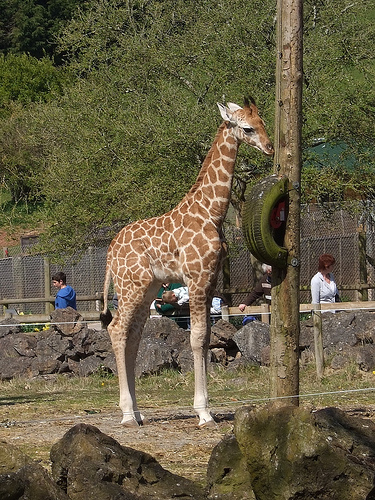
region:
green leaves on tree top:
[0, 53, 65, 109]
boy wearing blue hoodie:
[51, 271, 77, 307]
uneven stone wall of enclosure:
[0, 309, 373, 380]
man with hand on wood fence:
[222, 265, 271, 323]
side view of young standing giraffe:
[101, 93, 272, 427]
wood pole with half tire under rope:
[239, 0, 303, 402]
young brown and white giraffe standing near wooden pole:
[96, 90, 280, 433]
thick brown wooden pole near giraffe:
[267, 0, 307, 447]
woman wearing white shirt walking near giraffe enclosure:
[307, 250, 341, 320]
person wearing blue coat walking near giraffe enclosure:
[50, 267, 78, 322]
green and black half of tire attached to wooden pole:
[238, 171, 291, 270]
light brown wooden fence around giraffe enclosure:
[0, 298, 374, 388]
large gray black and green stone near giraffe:
[199, 397, 374, 498]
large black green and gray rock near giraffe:
[45, 420, 211, 498]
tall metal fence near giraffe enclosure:
[1, 223, 374, 325]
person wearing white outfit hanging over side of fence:
[160, 281, 211, 313]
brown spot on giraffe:
[115, 227, 124, 243]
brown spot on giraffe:
[124, 231, 132, 244]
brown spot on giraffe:
[131, 225, 147, 238]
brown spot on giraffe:
[130, 235, 152, 253]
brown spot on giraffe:
[116, 244, 132, 257]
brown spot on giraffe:
[140, 252, 151, 270]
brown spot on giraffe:
[131, 263, 140, 272]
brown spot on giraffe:
[184, 244, 200, 263]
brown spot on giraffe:
[180, 212, 203, 231]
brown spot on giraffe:
[190, 283, 196, 293]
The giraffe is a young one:
[92, 94, 289, 411]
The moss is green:
[234, 402, 328, 484]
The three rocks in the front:
[3, 407, 370, 493]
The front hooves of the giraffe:
[196, 409, 216, 432]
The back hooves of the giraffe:
[121, 409, 139, 427]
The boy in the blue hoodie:
[43, 271, 79, 312]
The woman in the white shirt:
[307, 244, 354, 305]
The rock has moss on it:
[227, 387, 347, 481]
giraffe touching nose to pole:
[191, 90, 302, 177]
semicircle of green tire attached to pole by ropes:
[240, 3, 300, 268]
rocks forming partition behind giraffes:
[0, 306, 366, 384]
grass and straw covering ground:
[1, 355, 362, 477]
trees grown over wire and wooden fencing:
[2, 7, 363, 292]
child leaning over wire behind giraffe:
[144, 276, 191, 315]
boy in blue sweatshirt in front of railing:
[45, 270, 78, 315]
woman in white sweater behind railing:
[307, 250, 337, 306]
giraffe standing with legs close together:
[106, 262, 220, 432]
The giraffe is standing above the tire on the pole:
[66, 92, 284, 430]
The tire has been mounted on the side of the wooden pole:
[243, 172, 321, 278]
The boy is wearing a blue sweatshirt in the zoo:
[40, 270, 82, 342]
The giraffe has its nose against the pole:
[67, 96, 313, 444]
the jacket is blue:
[52, 285, 76, 311]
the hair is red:
[316, 254, 336, 271]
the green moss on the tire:
[242, 172, 288, 264]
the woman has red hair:
[310, 253, 338, 305]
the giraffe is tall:
[100, 92, 274, 430]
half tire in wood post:
[238, 172, 298, 270]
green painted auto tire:
[235, 171, 290, 267]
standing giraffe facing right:
[82, 91, 281, 445]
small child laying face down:
[150, 278, 203, 305]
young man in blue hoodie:
[41, 269, 84, 315]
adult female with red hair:
[306, 248, 341, 313]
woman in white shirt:
[305, 251, 338, 305]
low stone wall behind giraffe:
[6, 304, 373, 383]